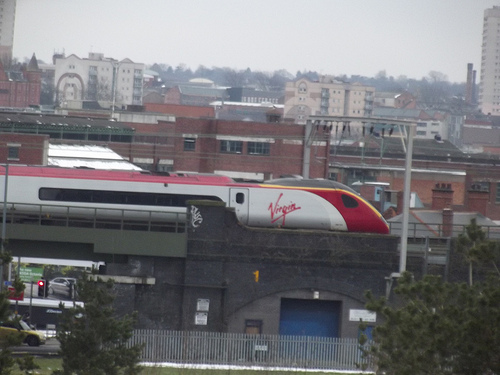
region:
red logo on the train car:
[264, 190, 306, 224]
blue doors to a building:
[278, 292, 336, 359]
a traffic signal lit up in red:
[32, 278, 47, 298]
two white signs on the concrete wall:
[192, 295, 212, 324]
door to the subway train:
[232, 185, 249, 222]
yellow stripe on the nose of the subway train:
[257, 178, 392, 227]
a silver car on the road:
[47, 273, 79, 295]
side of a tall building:
[478, 1, 498, 113]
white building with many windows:
[50, 50, 149, 105]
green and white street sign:
[9, 263, 47, 289]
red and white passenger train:
[0, 163, 395, 233]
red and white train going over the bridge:
[0, 164, 397, 240]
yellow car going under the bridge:
[0, 318, 39, 345]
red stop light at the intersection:
[36, 280, 48, 299]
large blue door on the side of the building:
[279, 299, 339, 362]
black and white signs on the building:
[193, 296, 210, 326]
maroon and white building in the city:
[50, 53, 142, 106]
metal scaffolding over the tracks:
[303, 114, 414, 285]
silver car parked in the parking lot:
[47, 277, 73, 298]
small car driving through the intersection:
[0, 314, 52, 349]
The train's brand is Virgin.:
[266, 193, 299, 227]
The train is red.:
[351, 213, 372, 228]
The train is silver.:
[303, 203, 324, 223]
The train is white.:
[332, 213, 341, 228]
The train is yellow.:
[262, 182, 335, 192]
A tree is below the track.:
[58, 280, 144, 374]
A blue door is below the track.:
[278, 299, 343, 334]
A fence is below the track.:
[142, 332, 245, 366]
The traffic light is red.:
[33, 278, 47, 290]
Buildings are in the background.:
[52, 51, 142, 109]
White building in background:
[52, 52, 143, 117]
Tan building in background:
[282, 76, 372, 128]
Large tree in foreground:
[354, 218, 499, 373]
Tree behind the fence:
[56, 273, 144, 374]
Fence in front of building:
[128, 327, 378, 369]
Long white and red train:
[0, 161, 388, 233]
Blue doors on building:
[277, 297, 339, 363]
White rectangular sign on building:
[347, 308, 377, 320]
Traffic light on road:
[28, 277, 44, 325]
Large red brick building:
[0, 109, 331, 179]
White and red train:
[0, 161, 391, 236]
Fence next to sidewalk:
[122, 326, 384, 369]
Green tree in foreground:
[352, 269, 498, 374]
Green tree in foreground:
[52, 270, 146, 374]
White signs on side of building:
[194, 293, 211, 328]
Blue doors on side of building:
[276, 295, 343, 361]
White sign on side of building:
[347, 306, 378, 324]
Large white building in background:
[52, 51, 142, 110]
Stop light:
[34, 272, 49, 299]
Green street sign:
[15, 265, 45, 284]